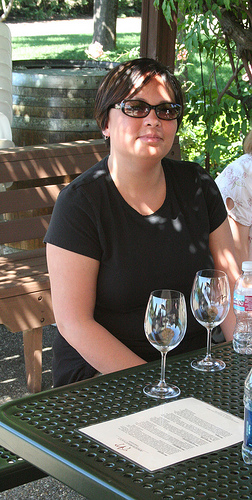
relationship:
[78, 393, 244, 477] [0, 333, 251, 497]
menu on table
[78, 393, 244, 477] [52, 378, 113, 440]
menu on table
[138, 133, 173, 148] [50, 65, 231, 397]
lips on woman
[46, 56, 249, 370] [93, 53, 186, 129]
woman has hair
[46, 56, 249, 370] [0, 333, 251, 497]
woman front table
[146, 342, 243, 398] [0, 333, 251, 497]
menu on table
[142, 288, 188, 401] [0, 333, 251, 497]
glass on table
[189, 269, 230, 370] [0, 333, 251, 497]
glass on table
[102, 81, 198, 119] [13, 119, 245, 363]
glass on table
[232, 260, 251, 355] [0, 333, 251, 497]
bottle on table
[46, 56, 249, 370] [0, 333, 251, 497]
woman at table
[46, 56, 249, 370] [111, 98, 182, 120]
woman wearing black sunglasses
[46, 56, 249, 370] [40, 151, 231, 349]
woman wearing shirt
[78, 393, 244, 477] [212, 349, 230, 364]
menu on table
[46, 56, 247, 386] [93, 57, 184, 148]
woman with hair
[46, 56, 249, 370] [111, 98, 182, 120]
woman has black sunglasses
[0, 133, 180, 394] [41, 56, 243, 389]
bench behind woman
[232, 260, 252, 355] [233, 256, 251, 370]
bottle of water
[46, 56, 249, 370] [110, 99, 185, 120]
woman wearing sunglasses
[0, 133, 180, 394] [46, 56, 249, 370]
bench behind a woman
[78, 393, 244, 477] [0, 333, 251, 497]
menu laying on table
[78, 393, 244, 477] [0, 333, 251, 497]
menu on top of table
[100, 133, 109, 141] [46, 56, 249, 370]
earing on woman